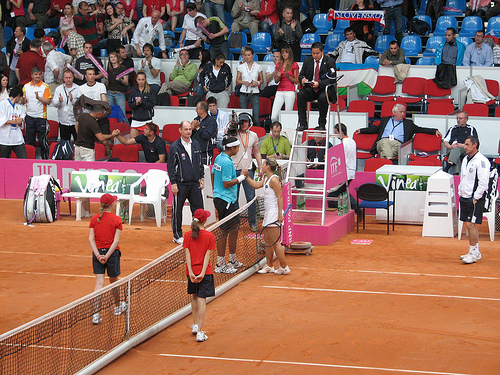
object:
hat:
[193, 209, 213, 221]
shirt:
[183, 228, 215, 274]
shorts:
[184, 272, 216, 297]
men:
[73, 103, 122, 162]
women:
[213, 135, 248, 272]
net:
[0, 197, 265, 375]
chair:
[353, 182, 396, 234]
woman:
[182, 208, 219, 343]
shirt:
[88, 211, 123, 250]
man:
[456, 136, 493, 265]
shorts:
[459, 196, 486, 225]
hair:
[190, 217, 202, 238]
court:
[0, 252, 499, 374]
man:
[232, 112, 262, 232]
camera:
[226, 111, 243, 142]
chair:
[127, 169, 169, 227]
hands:
[193, 275, 204, 283]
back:
[183, 231, 213, 271]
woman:
[243, 158, 291, 277]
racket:
[259, 201, 295, 247]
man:
[356, 104, 444, 161]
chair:
[354, 127, 381, 158]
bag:
[21, 174, 66, 224]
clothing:
[432, 63, 459, 88]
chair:
[465, 79, 499, 106]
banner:
[336, 61, 380, 96]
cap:
[100, 193, 118, 206]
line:
[293, 283, 500, 303]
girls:
[180, 208, 219, 345]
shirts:
[182, 230, 217, 275]